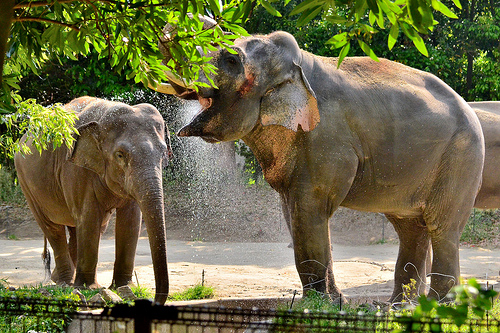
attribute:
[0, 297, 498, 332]
gate — wired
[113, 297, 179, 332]
pole — black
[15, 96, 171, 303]
elephant — young, walked, dirty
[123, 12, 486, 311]
elephant — spraying, big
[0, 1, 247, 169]
trees — green, brown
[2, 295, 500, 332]
fence — metal, black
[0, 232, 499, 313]
floor — dirt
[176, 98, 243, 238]
water — spraying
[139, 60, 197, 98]
tusk — ivory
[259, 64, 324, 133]
ear — split